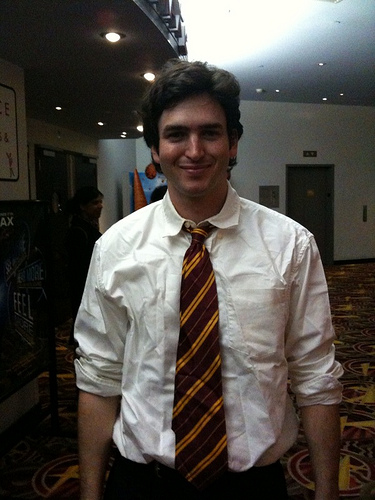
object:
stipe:
[190, 223, 212, 243]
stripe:
[172, 229, 227, 483]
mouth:
[178, 161, 213, 176]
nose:
[185, 136, 205, 161]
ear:
[141, 129, 169, 171]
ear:
[221, 119, 245, 174]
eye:
[202, 127, 222, 139]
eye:
[166, 128, 188, 140]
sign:
[303, 150, 317, 156]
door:
[282, 157, 348, 272]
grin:
[178, 161, 212, 176]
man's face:
[158, 89, 228, 195]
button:
[185, 220, 192, 230]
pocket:
[236, 287, 286, 365]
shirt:
[73, 180, 344, 474]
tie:
[170, 219, 231, 488]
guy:
[72, 60, 344, 500]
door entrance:
[283, 165, 338, 267]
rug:
[9, 259, 373, 498]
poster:
[129, 170, 169, 214]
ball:
[142, 158, 156, 180]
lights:
[46, 28, 350, 147]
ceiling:
[3, 3, 373, 138]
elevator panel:
[363, 206, 368, 222]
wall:
[246, 101, 373, 264]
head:
[141, 63, 243, 196]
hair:
[135, 61, 243, 155]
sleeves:
[74, 260, 130, 396]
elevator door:
[285, 163, 340, 264]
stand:
[0, 202, 59, 427]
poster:
[1, 206, 54, 398]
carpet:
[23, 257, 373, 495]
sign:
[1, 85, 19, 180]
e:
[3, 96, 13, 117]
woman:
[71, 187, 105, 319]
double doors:
[35, 142, 97, 232]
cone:
[132, 165, 153, 212]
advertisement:
[125, 171, 180, 215]